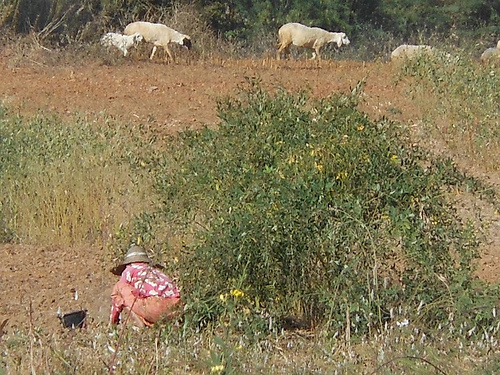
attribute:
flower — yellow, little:
[227, 286, 249, 300]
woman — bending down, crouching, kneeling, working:
[97, 243, 181, 338]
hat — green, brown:
[108, 241, 168, 275]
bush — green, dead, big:
[151, 73, 499, 346]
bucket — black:
[55, 308, 92, 331]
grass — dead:
[1, 241, 120, 338]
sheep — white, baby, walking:
[95, 29, 146, 57]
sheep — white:
[118, 20, 197, 61]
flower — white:
[392, 316, 411, 331]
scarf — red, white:
[115, 259, 187, 297]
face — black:
[181, 35, 195, 52]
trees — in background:
[1, 2, 497, 56]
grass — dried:
[6, 278, 495, 373]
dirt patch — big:
[0, 236, 121, 324]